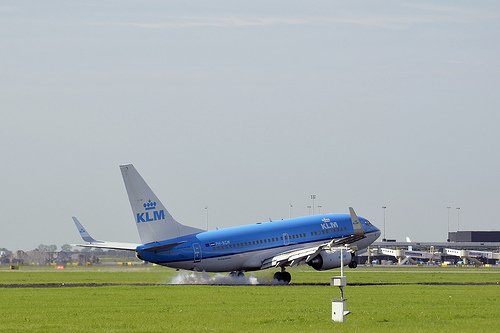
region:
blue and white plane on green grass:
[119, 156, 386, 291]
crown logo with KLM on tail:
[131, 192, 168, 224]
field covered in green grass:
[4, 266, 497, 328]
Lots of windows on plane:
[210, 223, 324, 251]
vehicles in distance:
[372, 235, 498, 267]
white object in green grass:
[326, 251, 353, 321]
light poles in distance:
[379, 198, 391, 238]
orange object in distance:
[54, 256, 66, 272]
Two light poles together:
[444, 200, 466, 237]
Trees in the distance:
[2, 238, 165, 266]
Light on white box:
[319, 255, 368, 325]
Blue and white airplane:
[106, 208, 381, 272]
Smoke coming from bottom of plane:
[174, 260, 289, 294]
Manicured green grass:
[110, 287, 316, 332]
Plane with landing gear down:
[226, 253, 368, 289]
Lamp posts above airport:
[384, 190, 464, 244]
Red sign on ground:
[51, 261, 67, 276]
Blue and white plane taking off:
[243, 212, 385, 296]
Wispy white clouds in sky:
[111, 3, 430, 56]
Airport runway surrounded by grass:
[16, 274, 117, 300]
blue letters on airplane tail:
[133, 198, 170, 228]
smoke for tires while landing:
[171, 270, 258, 285]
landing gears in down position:
[228, 270, 298, 285]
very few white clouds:
[121, 12, 476, 154]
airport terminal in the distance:
[387, 226, 499, 277]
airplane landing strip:
[26, 274, 499, 297]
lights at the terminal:
[281, 188, 473, 225]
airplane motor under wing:
[308, 245, 357, 275]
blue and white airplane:
[102, 154, 399, 293]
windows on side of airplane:
[212, 224, 349, 255]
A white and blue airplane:
[32, 108, 399, 293]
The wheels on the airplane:
[219, 263, 298, 285]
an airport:
[368, 224, 498, 271]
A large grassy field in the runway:
[1, 286, 498, 331]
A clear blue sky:
[4, 5, 499, 259]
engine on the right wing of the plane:
[310, 242, 365, 272]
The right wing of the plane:
[263, 205, 367, 265]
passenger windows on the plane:
[201, 225, 349, 256]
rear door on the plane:
[185, 241, 211, 270]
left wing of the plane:
[71, 214, 145, 259]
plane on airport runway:
[65, 152, 395, 305]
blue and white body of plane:
[227, 213, 340, 268]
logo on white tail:
[127, 191, 171, 233]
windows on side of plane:
[231, 230, 283, 252]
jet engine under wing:
[305, 239, 365, 282]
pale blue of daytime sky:
[271, 70, 365, 142]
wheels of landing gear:
[230, 265, 296, 289]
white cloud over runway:
[176, 269, 257, 294]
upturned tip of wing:
[61, 213, 113, 253]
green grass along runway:
[115, 286, 177, 325]